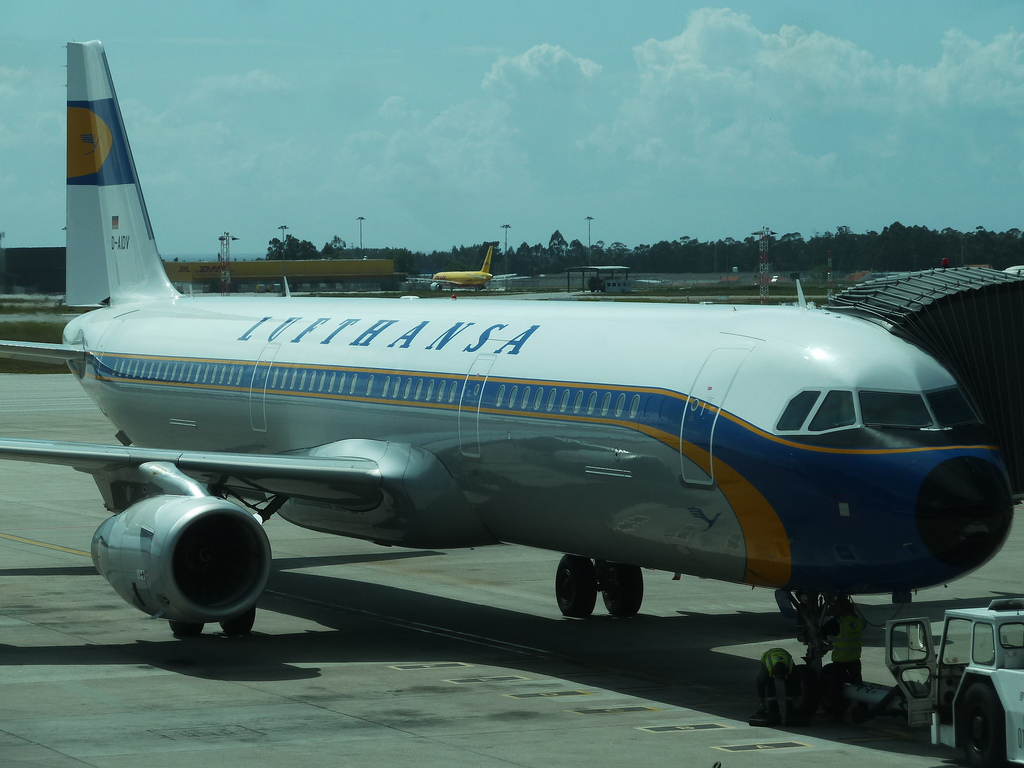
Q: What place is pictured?
A: It is a runway.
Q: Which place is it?
A: It is a runway.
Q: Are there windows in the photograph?
A: Yes, there are windows.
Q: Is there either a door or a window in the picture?
A: Yes, there are windows.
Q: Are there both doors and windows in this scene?
A: Yes, there are both windows and doors.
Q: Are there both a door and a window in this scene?
A: Yes, there are both a window and a door.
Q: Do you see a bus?
A: No, there are no buses.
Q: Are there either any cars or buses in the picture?
A: No, there are no buses or cars.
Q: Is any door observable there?
A: Yes, there is a door.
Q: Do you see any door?
A: Yes, there is a door.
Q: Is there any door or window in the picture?
A: Yes, there is a door.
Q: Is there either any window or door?
A: Yes, there is a door.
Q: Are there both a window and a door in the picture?
A: Yes, there are both a door and a window.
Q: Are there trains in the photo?
A: No, there are no trains.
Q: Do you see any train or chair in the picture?
A: No, there are no trains or chairs.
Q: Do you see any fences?
A: No, there are no fences.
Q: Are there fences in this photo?
A: No, there are no fences.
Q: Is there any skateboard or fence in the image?
A: No, there are no fences or skateboards.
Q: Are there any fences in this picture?
A: No, there are no fences.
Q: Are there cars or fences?
A: No, there are no fences or cars.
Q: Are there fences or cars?
A: No, there are no fences or cars.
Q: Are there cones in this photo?
A: No, there are no cones.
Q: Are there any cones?
A: No, there are no cones.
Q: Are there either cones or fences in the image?
A: No, there are no cones or fences.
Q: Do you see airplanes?
A: Yes, there is an airplane.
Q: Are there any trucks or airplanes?
A: Yes, there is an airplane.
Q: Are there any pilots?
A: No, there are no pilots.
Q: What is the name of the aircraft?
A: The aircraft is an airplane.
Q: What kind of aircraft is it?
A: The aircraft is an airplane.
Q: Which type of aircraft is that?
A: This is an airplane.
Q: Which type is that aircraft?
A: This is an airplane.